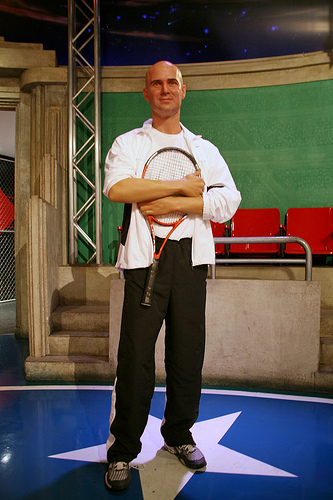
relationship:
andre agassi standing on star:
[103, 61, 243, 493] [44, 406, 301, 498]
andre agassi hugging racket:
[103, 61, 243, 493] [140, 147, 200, 307]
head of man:
[142, 61, 185, 83] [120, 55, 220, 187]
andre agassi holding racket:
[103, 61, 243, 490] [138, 147, 201, 307]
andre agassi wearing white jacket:
[103, 61, 243, 493] [103, 116, 243, 274]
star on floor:
[44, 406, 301, 498] [2, 382, 331, 498]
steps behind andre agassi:
[30, 257, 118, 377] [103, 61, 243, 493]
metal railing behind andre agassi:
[209, 229, 320, 287] [103, 61, 243, 493]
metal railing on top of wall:
[209, 229, 320, 287] [206, 264, 323, 389]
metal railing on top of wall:
[209, 229, 320, 287] [240, 72, 331, 201]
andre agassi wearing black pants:
[103, 61, 243, 493] [113, 226, 205, 465]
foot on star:
[157, 435, 207, 473] [44, 406, 301, 498]